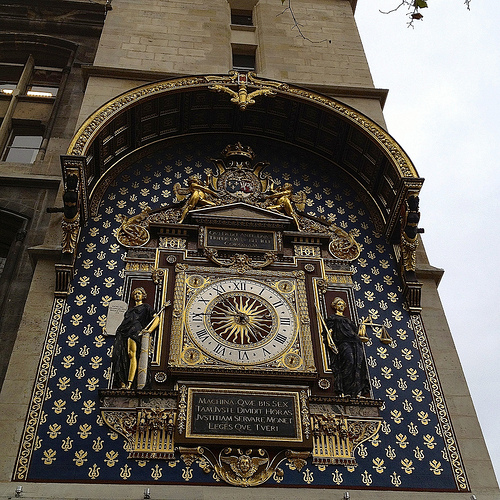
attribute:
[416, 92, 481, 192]
sky — light grey, cloudy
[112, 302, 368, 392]
robes — black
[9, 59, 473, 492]
design — blue, gold, ornate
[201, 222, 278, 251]
sign — illegible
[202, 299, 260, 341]
hands — black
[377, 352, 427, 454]
background — blue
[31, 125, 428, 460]
accents — gold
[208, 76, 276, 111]
bird. — golden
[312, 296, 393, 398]
figure — human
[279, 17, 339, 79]
wall — brown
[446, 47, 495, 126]
sky — cloudy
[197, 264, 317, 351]
clock — black